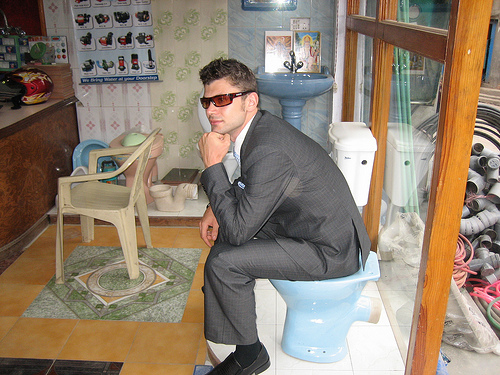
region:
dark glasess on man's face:
[181, 74, 253, 111]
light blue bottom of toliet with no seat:
[266, 264, 405, 359]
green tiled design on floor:
[13, 237, 205, 308]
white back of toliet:
[323, 114, 377, 191]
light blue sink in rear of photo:
[261, 57, 338, 122]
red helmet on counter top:
[10, 72, 75, 134]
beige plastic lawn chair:
[60, 126, 170, 291]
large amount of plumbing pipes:
[467, 193, 497, 258]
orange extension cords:
[453, 233, 480, 301]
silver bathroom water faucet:
[282, 48, 312, 76]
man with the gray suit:
[142, 53, 387, 355]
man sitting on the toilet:
[140, 37, 383, 373]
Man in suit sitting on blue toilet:
[195, 51, 381, 372]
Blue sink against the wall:
[252, 68, 333, 125]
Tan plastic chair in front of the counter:
[50, 127, 160, 286]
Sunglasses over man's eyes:
[198, 87, 253, 112]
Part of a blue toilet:
[272, 250, 382, 363]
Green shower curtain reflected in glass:
[388, 0, 409, 132]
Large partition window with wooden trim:
[343, 0, 485, 373]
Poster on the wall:
[65, 0, 158, 95]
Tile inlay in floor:
[20, 238, 205, 324]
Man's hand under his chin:
[197, 123, 234, 170]